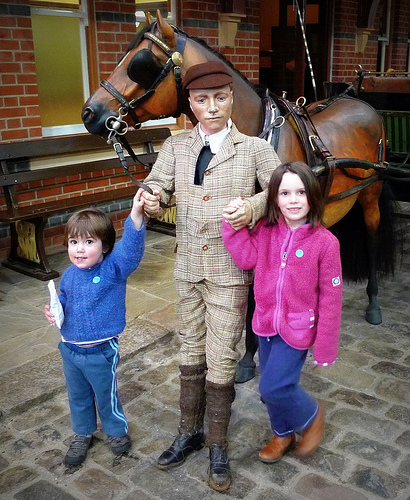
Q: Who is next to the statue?
A: Some kids.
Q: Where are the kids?
A: Next to the statue.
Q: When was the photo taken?
A: During the daytime.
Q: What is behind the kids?
A: A horse.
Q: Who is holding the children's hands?
A: The dummy.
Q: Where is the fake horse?
A: Behind the children.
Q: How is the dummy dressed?
A: As an english gentleman.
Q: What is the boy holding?
A: A snack bag.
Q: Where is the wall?
A: Behind the horse.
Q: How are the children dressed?
A: In fleeces.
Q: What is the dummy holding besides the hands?
A: The horse's reins.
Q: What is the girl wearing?
A: A fluffy pink jacket.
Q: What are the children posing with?
A: A statue of a man.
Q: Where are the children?
A: Outside of a building.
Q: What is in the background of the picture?
A: A brick building and a horse statue.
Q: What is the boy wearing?
A: Pants and a sweater.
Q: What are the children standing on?
A: A brick floor.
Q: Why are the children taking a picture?
A: To pose with the statue of a man and horse.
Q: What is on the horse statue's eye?
A: An eyepatch.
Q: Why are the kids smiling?
A: Posing for the photo.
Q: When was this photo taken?
A: In the daytime.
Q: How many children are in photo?
A: Two.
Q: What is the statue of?
A: A jockey.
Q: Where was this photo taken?
A: At a racetrack.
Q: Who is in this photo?
A: Two children.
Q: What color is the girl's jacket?
A: Pink.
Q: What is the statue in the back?
A: A horse.